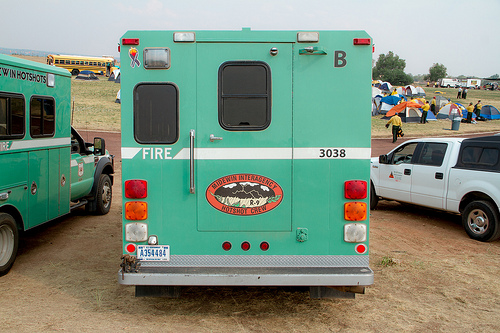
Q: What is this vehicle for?
A: Ambulance.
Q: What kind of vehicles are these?
A: Ambulance.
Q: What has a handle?
A: A door.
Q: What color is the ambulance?
A: Blue.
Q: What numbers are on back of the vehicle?
A: 3038.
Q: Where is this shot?
A: Park.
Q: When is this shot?
A: Daytime.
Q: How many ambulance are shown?
A: 2.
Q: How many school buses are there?
A: 1.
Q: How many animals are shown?
A: 0.